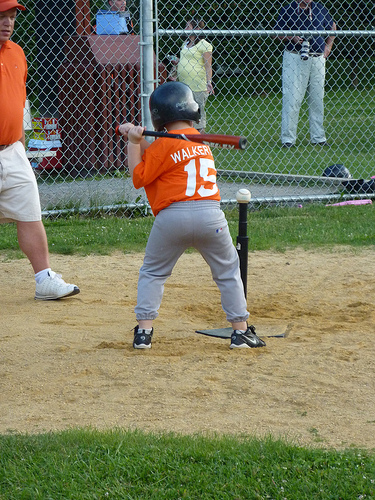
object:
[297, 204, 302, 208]
bat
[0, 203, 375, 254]
grass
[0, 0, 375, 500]
foreground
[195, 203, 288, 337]
tee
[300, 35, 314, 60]
camera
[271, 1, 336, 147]
blue shirt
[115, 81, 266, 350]
batter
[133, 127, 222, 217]
jersey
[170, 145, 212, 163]
walker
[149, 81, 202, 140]
helmet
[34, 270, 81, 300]
shoes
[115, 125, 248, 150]
bat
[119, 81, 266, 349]
stand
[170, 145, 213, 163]
word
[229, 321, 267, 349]
shoe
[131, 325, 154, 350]
shoe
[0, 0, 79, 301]
man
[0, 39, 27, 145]
shirt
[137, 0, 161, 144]
link fence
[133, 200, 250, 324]
pants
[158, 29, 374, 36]
metal pole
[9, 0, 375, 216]
chainlink fence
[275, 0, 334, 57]
shirt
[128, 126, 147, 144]
hand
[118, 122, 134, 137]
hand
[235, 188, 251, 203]
baseball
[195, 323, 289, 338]
home plate